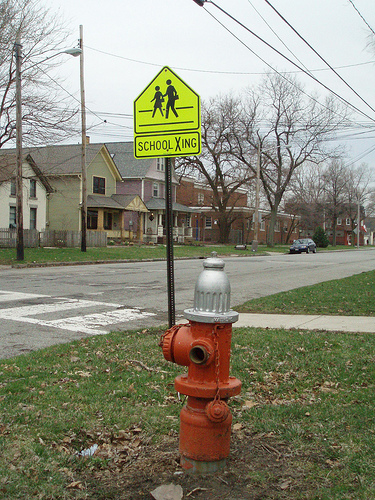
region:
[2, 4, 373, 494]
neighborhood on an overcast day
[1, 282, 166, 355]
old white and grey crosswalk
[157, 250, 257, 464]
skinny orange and silver fire hydrant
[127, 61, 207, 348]
bright yellow school crossing sign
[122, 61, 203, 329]
bright yellow "school Xing" sign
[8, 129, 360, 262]
differently colored houses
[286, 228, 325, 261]
Black car parked on the street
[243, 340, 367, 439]
dead leaves in the grass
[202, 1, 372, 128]
power lines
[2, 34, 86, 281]
one street light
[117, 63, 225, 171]
People cross the street here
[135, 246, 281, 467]
A red fire hydrant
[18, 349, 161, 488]
Grass is full of leaves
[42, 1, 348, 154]
Sky is cloudy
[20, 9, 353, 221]
Photo was taken during the day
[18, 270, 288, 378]
It has rained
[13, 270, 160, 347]
Whit paint is fading away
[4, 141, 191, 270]
Houses along the street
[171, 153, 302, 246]
This is a school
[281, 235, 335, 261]
A black car is parked here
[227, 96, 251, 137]
branches of a tree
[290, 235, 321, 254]
a car on the road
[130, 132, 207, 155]
a yellow and black school crossing sign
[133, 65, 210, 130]
a yellow and black school crossing sign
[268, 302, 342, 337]
a cement sidewalk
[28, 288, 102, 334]
a marked crosswalk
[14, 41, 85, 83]
a street light on a pole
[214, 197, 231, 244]
a trunk of a tree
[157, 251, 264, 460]
a red and silver fire hydrant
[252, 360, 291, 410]
leaves in the grass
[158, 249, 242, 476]
Fire hydrant on the grass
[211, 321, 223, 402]
Chain on the fire hydrant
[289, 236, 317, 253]
Black car parked on the road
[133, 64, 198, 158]
Road sign on the side of the road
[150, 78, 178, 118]
People on the road sign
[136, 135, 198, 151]
Words on the road sign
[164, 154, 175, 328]
Metal stick with a sign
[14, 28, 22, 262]
Electric pole on the side of the road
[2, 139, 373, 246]
Buildings with different colors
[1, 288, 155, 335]
White marks on the road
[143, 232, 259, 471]
orange and silver fire hydrant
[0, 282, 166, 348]
white lines on street indicate crosswalk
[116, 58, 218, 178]
sign says "school X-ing"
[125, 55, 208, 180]
yellow sign with black letters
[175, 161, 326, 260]
brick building in the background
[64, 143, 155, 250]
green house has sun rays design in the front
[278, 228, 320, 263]
one car parked at the curb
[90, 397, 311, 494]
patch of brown dirt surrounds the fire hydrant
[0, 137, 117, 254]
wooden fence surrounds the beige house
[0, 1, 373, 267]
the trees have no leaves